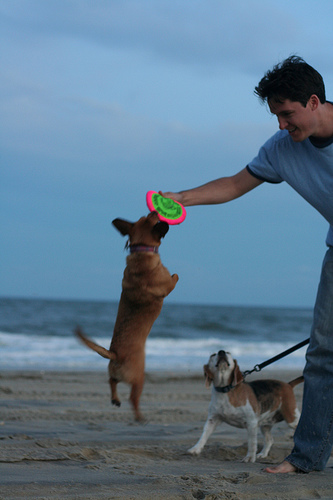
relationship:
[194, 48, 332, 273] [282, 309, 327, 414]
guy has pant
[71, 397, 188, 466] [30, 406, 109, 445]
track in sand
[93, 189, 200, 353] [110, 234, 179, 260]
dog has blue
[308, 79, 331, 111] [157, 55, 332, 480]
ear on guy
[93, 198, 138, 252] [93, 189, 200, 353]
ear on dog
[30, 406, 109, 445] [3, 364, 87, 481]
sand on beach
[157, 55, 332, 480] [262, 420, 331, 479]
guy has foot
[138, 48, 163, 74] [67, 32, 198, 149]
part of sky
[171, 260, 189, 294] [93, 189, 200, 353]
paw on dog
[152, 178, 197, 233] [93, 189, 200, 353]
frisbee with dog